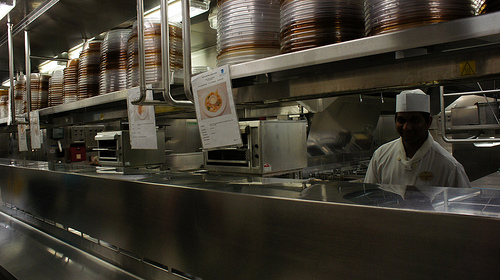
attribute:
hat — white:
[395, 88, 431, 113]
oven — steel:
[91, 126, 126, 168]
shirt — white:
[361, 130, 471, 189]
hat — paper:
[394, 86, 436, 113]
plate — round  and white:
[201, 90, 226, 117]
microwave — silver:
[151, 96, 343, 223]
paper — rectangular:
[88, 51, 312, 168]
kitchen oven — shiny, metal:
[202, 107, 317, 179]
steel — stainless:
[2, 156, 494, 279]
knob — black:
[251, 139, 261, 168]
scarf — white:
[366, 136, 452, 178]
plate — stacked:
[217, 42, 283, 52]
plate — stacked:
[277, 19, 362, 29]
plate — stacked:
[73, 65, 100, 74]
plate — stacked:
[129, 54, 187, 58]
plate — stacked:
[47, 85, 63, 90]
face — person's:
[393, 112, 432, 139]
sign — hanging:
[183, 62, 243, 154]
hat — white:
[391, 85, 430, 109]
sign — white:
[123, 82, 158, 152]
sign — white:
[190, 62, 244, 152]